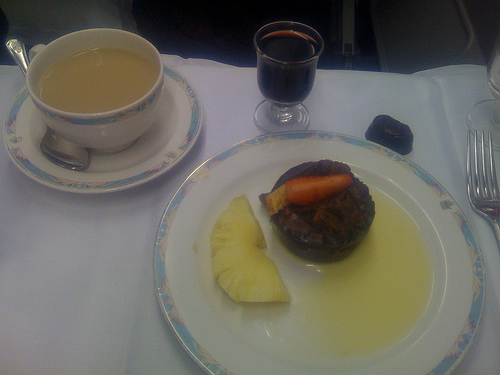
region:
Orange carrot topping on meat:
[254, 168, 361, 225]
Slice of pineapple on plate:
[194, 190, 301, 320]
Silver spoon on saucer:
[7, 35, 94, 187]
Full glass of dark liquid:
[241, 11, 322, 136]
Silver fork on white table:
[457, 120, 496, 273]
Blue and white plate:
[151, 127, 497, 373]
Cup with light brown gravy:
[22, 28, 174, 168]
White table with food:
[1, 36, 497, 374]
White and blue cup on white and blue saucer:
[25, 31, 172, 154]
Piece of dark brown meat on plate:
[254, 148, 386, 274]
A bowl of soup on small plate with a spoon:
[4, 25, 201, 187]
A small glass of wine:
[249, 25, 332, 134]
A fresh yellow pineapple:
[203, 195, 275, 307]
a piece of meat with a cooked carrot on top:
[265, 160, 377, 259]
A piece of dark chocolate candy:
[365, 112, 421, 152]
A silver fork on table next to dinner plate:
[375, 123, 498, 323]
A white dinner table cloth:
[14, 165, 198, 373]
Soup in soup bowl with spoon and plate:
[3, 35, 102, 165]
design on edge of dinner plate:
[150, 197, 214, 359]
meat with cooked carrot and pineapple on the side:
[207, 157, 383, 311]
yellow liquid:
[329, 271, 404, 328]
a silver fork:
[460, 135, 499, 201]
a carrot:
[296, 173, 338, 198]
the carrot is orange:
[287, 178, 352, 197]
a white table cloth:
[20, 228, 119, 341]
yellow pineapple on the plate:
[202, 211, 282, 299]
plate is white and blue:
[407, 343, 465, 369]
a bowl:
[102, 115, 139, 141]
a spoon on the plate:
[32, 140, 93, 170]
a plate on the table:
[114, 149, 157, 180]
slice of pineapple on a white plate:
[208, 194, 287, 304]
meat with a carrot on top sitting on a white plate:
[259, 160, 375, 263]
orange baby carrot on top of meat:
[259, 172, 354, 214]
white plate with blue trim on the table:
[153, 128, 486, 374]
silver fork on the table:
[465, 128, 498, 245]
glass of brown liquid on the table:
[253, 20, 326, 137]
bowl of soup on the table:
[26, 29, 166, 154]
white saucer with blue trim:
[4, 63, 204, 193]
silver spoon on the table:
[4, 36, 92, 173]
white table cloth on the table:
[2, 55, 498, 373]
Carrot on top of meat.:
[265, 153, 374, 260]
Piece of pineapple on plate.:
[205, 189, 291, 319]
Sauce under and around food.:
[284, 160, 439, 363]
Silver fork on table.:
[464, 122, 499, 336]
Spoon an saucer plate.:
[0, 27, 101, 197]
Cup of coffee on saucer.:
[3, 24, 205, 198]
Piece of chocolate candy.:
[362, 112, 417, 157]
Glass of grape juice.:
[250, 19, 331, 132]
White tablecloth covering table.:
[3, 52, 496, 372]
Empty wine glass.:
[466, 37, 497, 148]